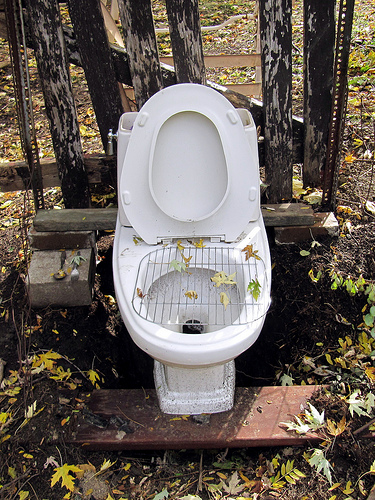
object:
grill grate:
[131, 246, 269, 326]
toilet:
[112, 209, 271, 416]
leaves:
[185, 290, 198, 300]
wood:
[68, 383, 333, 451]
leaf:
[51, 463, 83, 493]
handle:
[106, 129, 117, 156]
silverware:
[54, 251, 67, 279]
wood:
[31, 201, 314, 231]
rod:
[322, 0, 355, 210]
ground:
[2, 0, 373, 499]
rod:
[3, 0, 45, 212]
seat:
[120, 83, 258, 246]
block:
[24, 249, 96, 308]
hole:
[182, 320, 203, 334]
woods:
[300, 1, 333, 185]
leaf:
[70, 256, 86, 265]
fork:
[71, 250, 80, 282]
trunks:
[24, 0, 89, 207]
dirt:
[32, 242, 364, 387]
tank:
[117, 111, 261, 226]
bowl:
[112, 227, 272, 352]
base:
[153, 359, 236, 415]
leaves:
[247, 278, 262, 302]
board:
[64, 384, 331, 450]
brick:
[274, 211, 339, 242]